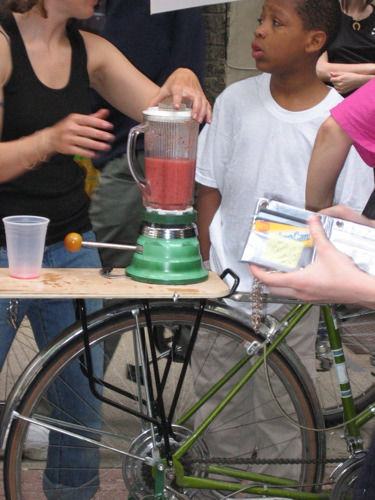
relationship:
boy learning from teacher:
[192, 0, 374, 498] [0, 0, 218, 496]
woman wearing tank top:
[5, 8, 116, 175] [9, 49, 92, 124]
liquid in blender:
[144, 156, 196, 208] [121, 101, 212, 284]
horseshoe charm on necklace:
[352, 20, 360, 31] [344, 5, 369, 31]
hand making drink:
[45, 104, 118, 162] [121, 100, 201, 214]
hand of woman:
[45, 104, 118, 162] [5, 8, 116, 175]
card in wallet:
[252, 218, 318, 246] [234, 196, 371, 294]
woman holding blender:
[5, 8, 116, 175] [121, 101, 212, 284]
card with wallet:
[252, 218, 318, 246] [238, 189, 370, 300]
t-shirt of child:
[193, 70, 373, 319] [194, 3, 368, 494]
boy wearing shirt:
[192, 0, 374, 498] [192, 68, 374, 322]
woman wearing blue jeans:
[5, 8, 116, 175] [1, 228, 110, 492]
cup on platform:
[3, 213, 51, 279] [0, 267, 231, 301]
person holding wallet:
[243, 194, 362, 320] [242, 193, 374, 283]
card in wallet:
[252, 218, 318, 246] [210, 181, 373, 307]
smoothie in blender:
[140, 155, 194, 208] [121, 101, 212, 284]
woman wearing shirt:
[5, 8, 116, 175] [11, 36, 110, 237]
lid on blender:
[144, 100, 193, 120] [62, 102, 210, 285]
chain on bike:
[136, 442, 360, 493] [7, 275, 373, 495]